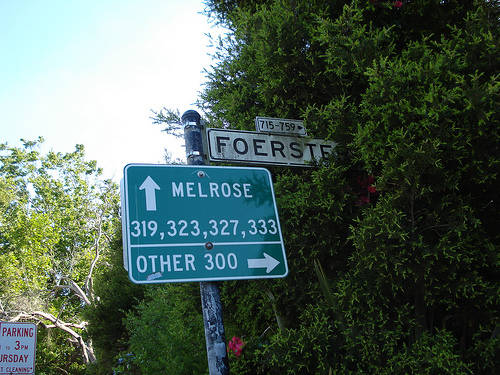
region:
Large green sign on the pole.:
[89, 129, 299, 293]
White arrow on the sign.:
[134, 166, 171, 219]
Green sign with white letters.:
[118, 140, 295, 291]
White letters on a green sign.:
[167, 178, 256, 206]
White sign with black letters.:
[211, 130, 345, 167]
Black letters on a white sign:
[201, 133, 342, 159]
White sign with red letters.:
[2, 311, 48, 373]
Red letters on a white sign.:
[0, 308, 48, 374]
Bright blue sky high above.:
[7, 70, 46, 117]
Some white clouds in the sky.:
[33, 89, 146, 140]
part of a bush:
[466, 183, 476, 196]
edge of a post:
[247, 273, 265, 309]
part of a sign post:
[251, 150, 261, 183]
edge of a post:
[198, 296, 213, 337]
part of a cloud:
[79, 174, 96, 207]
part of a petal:
[353, 276, 358, 303]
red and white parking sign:
[0, 320, 39, 374]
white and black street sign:
[254, 114, 308, 135]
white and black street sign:
[208, 127, 338, 169]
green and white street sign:
[122, 161, 290, 285]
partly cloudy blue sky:
[0, 1, 236, 223]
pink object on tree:
[226, 334, 243, 354]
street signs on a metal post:
[120, 113, 341, 374]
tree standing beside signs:
[2, 135, 119, 374]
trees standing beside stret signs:
[116, 1, 499, 374]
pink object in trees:
[350, 171, 377, 208]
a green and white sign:
[123, 164, 288, 282]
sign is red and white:
[1, 323, 34, 374]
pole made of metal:
[182, 109, 228, 374]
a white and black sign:
[206, 117, 341, 167]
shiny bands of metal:
[184, 120, 201, 156]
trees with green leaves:
[1, 0, 498, 372]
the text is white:
[131, 181, 277, 269]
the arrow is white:
[140, 175, 160, 211]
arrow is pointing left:
[247, 251, 279, 271]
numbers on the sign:
[257, 118, 296, 134]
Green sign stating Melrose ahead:
[114, 152, 292, 292]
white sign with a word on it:
[211, 113, 343, 170]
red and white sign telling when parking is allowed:
[1, 314, 43, 373]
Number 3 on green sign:
[129, 218, 141, 243]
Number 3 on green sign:
[167, 221, 177, 241]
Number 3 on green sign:
[190, 216, 201, 240]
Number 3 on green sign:
[208, 218, 219, 238]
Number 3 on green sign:
[248, 220, 258, 237]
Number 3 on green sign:
[258, 217, 268, 237]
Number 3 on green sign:
[268, 216, 277, 236]